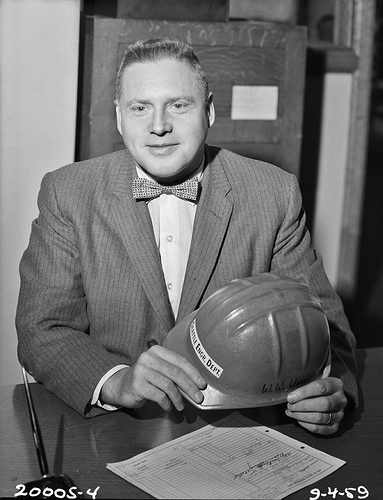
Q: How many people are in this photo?
A: One.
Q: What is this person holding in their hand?
A: A hard hat.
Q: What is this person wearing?
A: A suit and bow-tie.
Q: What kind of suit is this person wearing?
A: A pinstripe suit.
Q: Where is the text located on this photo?
A: In the left and right lower corners.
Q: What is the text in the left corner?
A: 20005-4.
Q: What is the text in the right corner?
A: 9-4-59.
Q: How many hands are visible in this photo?
A: Two.